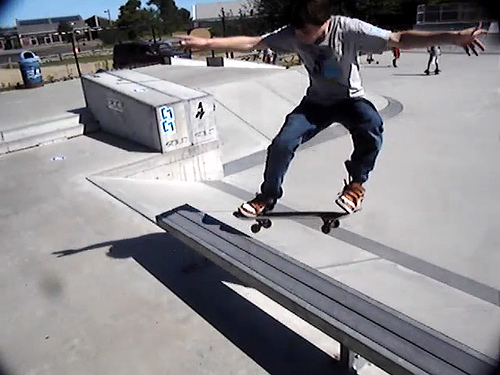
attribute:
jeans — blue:
[251, 97, 386, 204]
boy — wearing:
[165, 4, 489, 235]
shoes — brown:
[235, 179, 369, 221]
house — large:
[20, 9, 102, 47]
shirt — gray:
[264, 15, 394, 102]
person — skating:
[421, 43, 451, 80]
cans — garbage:
[14, 43, 47, 87]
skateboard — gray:
[235, 208, 352, 231]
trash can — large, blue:
[9, 44, 56, 94]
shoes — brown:
[233, 184, 370, 221]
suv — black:
[111, 34, 192, 65]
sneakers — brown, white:
[236, 177, 365, 227]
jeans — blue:
[258, 97, 383, 199]